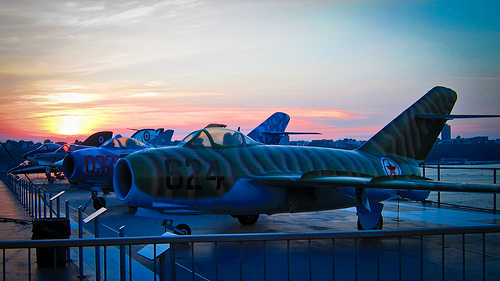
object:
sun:
[45, 112, 102, 134]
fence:
[0, 223, 500, 279]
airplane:
[113, 85, 499, 234]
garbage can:
[31, 216, 82, 279]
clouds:
[0, 1, 27, 15]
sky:
[0, 0, 500, 115]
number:
[164, 156, 225, 191]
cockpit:
[180, 125, 261, 147]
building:
[442, 122, 453, 140]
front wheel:
[173, 224, 191, 235]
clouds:
[170, 110, 218, 122]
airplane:
[61, 128, 152, 211]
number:
[82, 154, 116, 175]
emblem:
[380, 156, 403, 175]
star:
[386, 160, 398, 175]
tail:
[357, 87, 498, 153]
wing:
[251, 171, 498, 189]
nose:
[113, 155, 158, 206]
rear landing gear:
[354, 203, 384, 229]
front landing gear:
[159, 221, 191, 236]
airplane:
[13, 142, 94, 183]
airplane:
[21, 141, 63, 158]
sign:
[82, 206, 108, 224]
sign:
[49, 190, 66, 201]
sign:
[137, 231, 182, 260]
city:
[288, 124, 499, 161]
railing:
[3, 178, 56, 218]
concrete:
[15, 197, 499, 280]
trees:
[344, 138, 350, 146]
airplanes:
[21, 85, 500, 228]